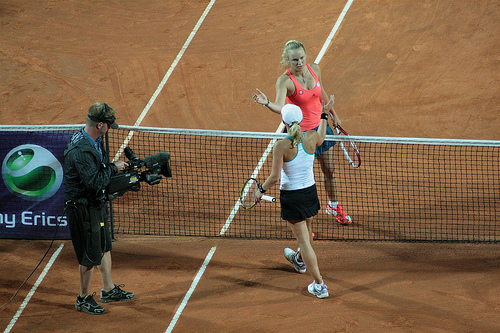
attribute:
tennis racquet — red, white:
[327, 110, 365, 170]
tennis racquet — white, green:
[236, 176, 277, 212]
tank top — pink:
[283, 62, 323, 128]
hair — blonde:
[279, 40, 307, 68]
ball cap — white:
[279, 104, 304, 126]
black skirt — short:
[276, 185, 321, 223]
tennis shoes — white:
[281, 245, 331, 303]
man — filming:
[63, 102, 134, 311]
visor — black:
[86, 104, 121, 132]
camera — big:
[90, 148, 174, 198]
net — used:
[1, 123, 499, 244]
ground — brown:
[2, 1, 500, 332]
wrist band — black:
[320, 111, 331, 120]